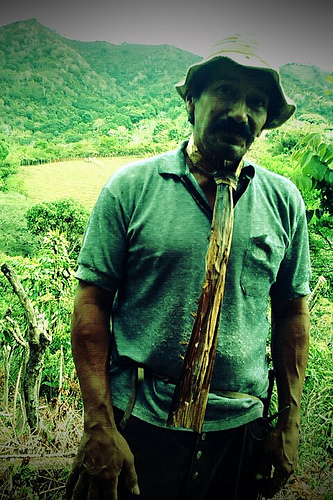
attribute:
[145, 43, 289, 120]
hat — bucket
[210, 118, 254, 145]
mustache — bushy